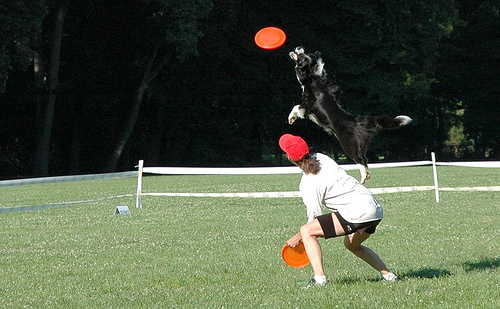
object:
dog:
[288, 47, 412, 185]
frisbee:
[254, 27, 286, 50]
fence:
[0, 152, 500, 216]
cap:
[279, 134, 309, 161]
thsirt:
[298, 153, 383, 222]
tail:
[359, 115, 412, 131]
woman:
[278, 134, 396, 290]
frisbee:
[282, 242, 310, 268]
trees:
[1, 0, 96, 175]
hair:
[297, 155, 322, 175]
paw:
[288, 105, 299, 124]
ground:
[0, 165, 500, 308]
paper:
[113, 205, 130, 214]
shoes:
[300, 279, 328, 290]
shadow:
[332, 269, 451, 283]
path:
[441, 108, 480, 158]